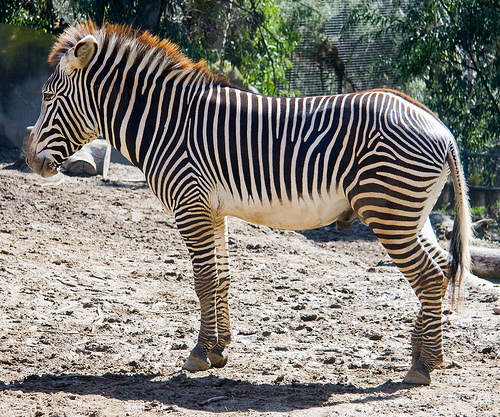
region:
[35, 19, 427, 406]
A black and white zebra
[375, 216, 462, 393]
A black and white zebra's feet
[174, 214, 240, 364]
A black and white zebra's feet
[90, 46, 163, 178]
A black and white zebra's neck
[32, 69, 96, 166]
A black and white zebra's head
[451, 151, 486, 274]
A black and white zebra's tail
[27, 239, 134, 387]
A brown muddy ground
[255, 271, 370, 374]
A brown muddy ground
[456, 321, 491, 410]
A brown muddy ground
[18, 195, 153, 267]
A brown muddy ground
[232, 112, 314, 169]
black and white stripes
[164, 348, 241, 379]
hoofs on the zebra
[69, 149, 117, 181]
rocks behind the zebra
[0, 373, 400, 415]
shadow of the zebra on the ground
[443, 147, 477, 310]
tail of the zebra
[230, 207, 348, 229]
white on the underbelly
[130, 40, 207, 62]
brown mane on the zebra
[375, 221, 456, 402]
legs on the zebra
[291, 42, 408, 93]
protective fencing in the back ground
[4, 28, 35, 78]
grass on the rock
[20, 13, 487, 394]
zebra standing in the sand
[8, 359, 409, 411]
shadow in the sand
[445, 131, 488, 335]
tail of a zebra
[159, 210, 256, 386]
front legs of a zebra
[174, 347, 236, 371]
hooves of a zebra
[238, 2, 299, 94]
green leaves of a tree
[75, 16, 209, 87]
mane on a zebra's neck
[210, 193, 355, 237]
belly of a zebra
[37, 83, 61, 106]
left eye of a zebra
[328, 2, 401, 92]
fence behind the trees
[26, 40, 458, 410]
the horse is stripes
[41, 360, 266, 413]
shadow on the ground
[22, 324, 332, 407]
shadow on the ground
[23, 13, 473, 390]
black and white striped zebra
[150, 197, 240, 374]
black and white striped zebra legs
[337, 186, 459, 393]
black and white striped zebra legs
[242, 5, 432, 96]
mesh wire fencing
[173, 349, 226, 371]
dirty black zebra hoof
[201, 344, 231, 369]
dirty black zebra hoof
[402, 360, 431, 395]
dirty black zebra hoof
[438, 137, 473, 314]
hairy black and white zebra tail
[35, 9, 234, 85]
spiky black zebra mane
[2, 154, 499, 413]
muddy grey ground